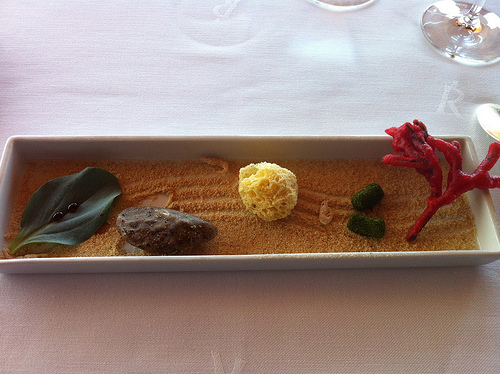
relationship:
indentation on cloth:
[170, 12, 308, 50] [94, 19, 261, 86]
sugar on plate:
[464, 84, 497, 132] [188, 2, 269, 49]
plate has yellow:
[188, 2, 269, 49] [252, 182, 290, 203]